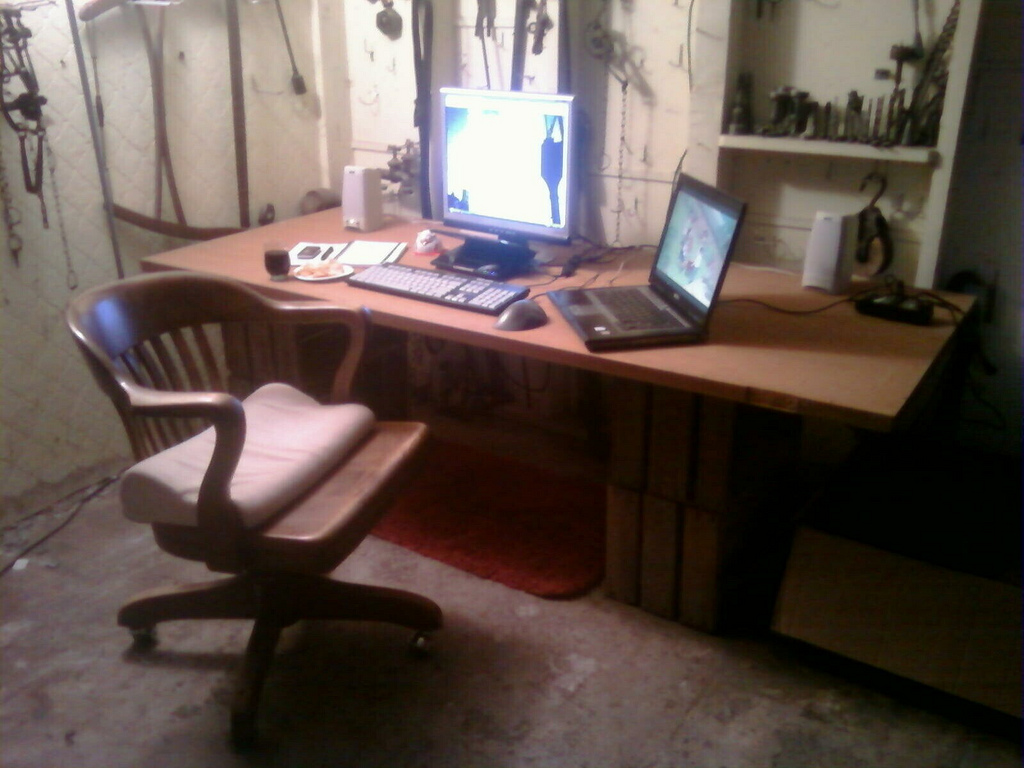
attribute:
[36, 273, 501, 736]
chair — brown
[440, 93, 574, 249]
screen — small, grey, computer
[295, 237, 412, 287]
paper — bunch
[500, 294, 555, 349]
mouse — grey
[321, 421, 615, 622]
rug — square, red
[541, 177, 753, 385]
laptop — black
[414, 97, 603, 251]
monitor — grey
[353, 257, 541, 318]
keyboard — black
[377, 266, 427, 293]
keys — white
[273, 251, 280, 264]
drink — dark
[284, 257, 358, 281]
plate — small, white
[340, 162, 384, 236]
speaker — grey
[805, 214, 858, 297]
speaker — grey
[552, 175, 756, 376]
computer — laptop, open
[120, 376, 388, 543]
cushion — flat, white, seat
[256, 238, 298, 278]
glass — beverage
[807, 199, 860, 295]
speaker — cream colored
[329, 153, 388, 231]
speaker — cream colored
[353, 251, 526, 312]
keyboard — black, white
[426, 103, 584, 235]
screen — large, operating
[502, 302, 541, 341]
mouse — small, black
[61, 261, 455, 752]
chair — brown, wooden, rolling, swiveling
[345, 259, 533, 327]
keyboard — black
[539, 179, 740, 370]
laptop — black